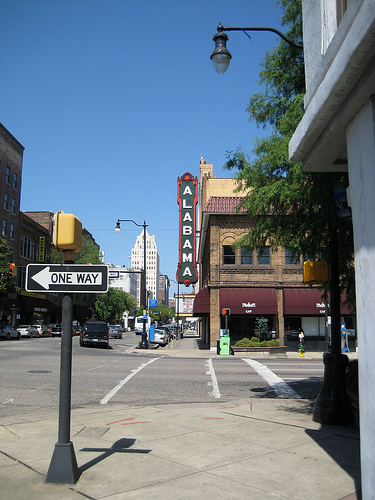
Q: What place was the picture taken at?
A: It was taken at the road.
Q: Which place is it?
A: It is a road.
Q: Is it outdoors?
A: Yes, it is outdoors.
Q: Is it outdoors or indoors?
A: It is outdoors.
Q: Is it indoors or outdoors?
A: It is outdoors.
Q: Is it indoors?
A: No, it is outdoors.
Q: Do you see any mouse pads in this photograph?
A: No, there are no mouse pads.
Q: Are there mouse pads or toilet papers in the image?
A: No, there are no mouse pads or toilet papers.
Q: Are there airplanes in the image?
A: No, there are no airplanes.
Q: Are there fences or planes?
A: No, there are no planes or fences.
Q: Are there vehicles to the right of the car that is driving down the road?
A: Yes, there is a vehicle to the right of the car.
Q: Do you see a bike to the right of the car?
A: No, there is a vehicle to the right of the car.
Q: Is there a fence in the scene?
A: No, there are no fences.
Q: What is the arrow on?
A: The arrow is on the pole.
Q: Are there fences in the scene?
A: No, there are no fences.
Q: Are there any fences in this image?
A: No, there are no fences.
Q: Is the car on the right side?
A: No, the car is on the left of the image.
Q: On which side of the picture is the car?
A: The car is on the left of the image.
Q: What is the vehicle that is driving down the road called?
A: The vehicle is a car.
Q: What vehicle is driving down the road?
A: The vehicle is a car.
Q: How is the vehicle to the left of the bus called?
A: The vehicle is a car.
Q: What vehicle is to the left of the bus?
A: The vehicle is a car.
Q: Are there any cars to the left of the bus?
A: Yes, there is a car to the left of the bus.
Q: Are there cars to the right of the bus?
A: No, the car is to the left of the bus.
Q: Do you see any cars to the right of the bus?
A: No, the car is to the left of the bus.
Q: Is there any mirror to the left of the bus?
A: No, there is a car to the left of the bus.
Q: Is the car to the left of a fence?
A: No, the car is to the left of a bus.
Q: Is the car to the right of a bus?
A: No, the car is to the left of a bus.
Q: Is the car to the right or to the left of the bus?
A: The car is to the left of the bus.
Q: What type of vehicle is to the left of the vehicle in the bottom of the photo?
A: The vehicle is a car.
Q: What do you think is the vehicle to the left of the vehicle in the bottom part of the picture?
A: The vehicle is a car.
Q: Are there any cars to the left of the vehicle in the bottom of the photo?
A: Yes, there is a car to the left of the vehicle.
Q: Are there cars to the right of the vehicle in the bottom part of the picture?
A: No, the car is to the left of the vehicle.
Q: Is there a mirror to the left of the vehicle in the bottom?
A: No, there is a car to the left of the vehicle.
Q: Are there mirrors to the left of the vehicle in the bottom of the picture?
A: No, there is a car to the left of the vehicle.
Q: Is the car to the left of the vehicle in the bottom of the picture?
A: Yes, the car is to the left of the vehicle.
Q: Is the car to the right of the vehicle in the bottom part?
A: No, the car is to the left of the vehicle.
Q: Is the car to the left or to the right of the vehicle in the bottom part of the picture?
A: The car is to the left of the vehicle.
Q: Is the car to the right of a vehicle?
A: Yes, the car is to the right of a vehicle.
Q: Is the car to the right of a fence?
A: No, the car is to the right of a vehicle.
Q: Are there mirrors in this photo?
A: No, there are no mirrors.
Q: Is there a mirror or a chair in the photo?
A: No, there are no mirrors or chairs.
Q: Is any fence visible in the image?
A: No, there are no fences.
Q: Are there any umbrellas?
A: No, there are no umbrellas.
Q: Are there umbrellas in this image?
A: No, there are no umbrellas.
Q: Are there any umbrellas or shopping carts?
A: No, there are no umbrellas or shopping carts.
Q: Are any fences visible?
A: No, there are no fences.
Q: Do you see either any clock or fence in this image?
A: No, there are no fences or clocks.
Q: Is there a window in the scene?
A: Yes, there is a window.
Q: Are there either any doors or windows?
A: Yes, there is a window.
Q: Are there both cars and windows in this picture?
A: Yes, there are both a window and a car.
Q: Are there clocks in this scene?
A: No, there are no clocks.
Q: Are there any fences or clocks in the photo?
A: No, there are no clocks or fences.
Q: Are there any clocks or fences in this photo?
A: No, there are no clocks or fences.